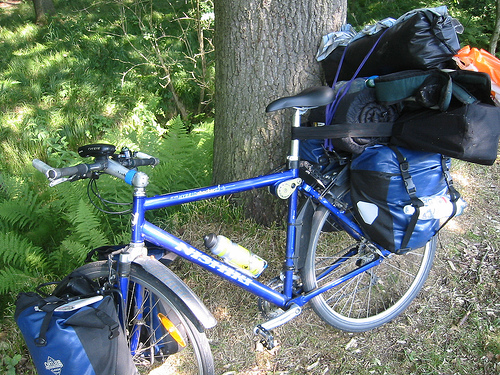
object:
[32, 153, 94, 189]
handlebars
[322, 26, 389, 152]
blue cord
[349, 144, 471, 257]
bag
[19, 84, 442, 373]
bicycle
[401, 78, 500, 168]
bags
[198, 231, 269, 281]
water bottle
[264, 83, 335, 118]
seat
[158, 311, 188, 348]
reflector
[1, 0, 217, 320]
grass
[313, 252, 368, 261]
spokes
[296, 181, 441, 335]
rear wheel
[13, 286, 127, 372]
bag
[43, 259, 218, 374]
front tire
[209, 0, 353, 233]
tree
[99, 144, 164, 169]
handlebars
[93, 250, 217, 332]
fender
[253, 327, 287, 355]
pedal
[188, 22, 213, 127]
bush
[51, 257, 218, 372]
wheel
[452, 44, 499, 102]
items